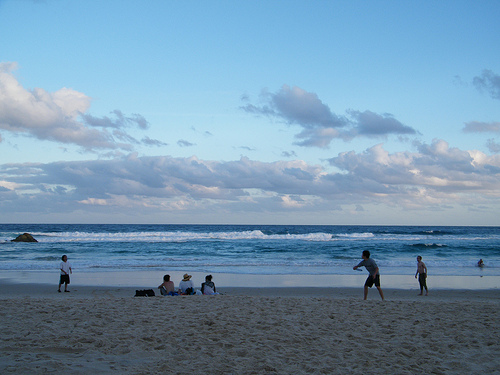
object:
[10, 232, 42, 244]
large rocks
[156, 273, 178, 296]
person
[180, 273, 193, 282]
hat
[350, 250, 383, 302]
man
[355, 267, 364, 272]
frisbee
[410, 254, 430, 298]
man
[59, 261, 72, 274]
shirt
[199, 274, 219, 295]
person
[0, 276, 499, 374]
beach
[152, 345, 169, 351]
footprints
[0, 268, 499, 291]
shore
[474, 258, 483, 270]
person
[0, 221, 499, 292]
water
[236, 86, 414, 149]
clouds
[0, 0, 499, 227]
sky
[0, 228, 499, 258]
waves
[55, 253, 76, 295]
man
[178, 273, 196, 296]
person